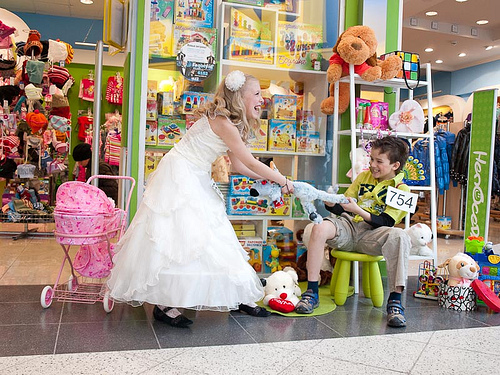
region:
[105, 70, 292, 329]
Blonde girl in a white dress.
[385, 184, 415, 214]
Number 754 on the side of a boy.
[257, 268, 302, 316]
White bear on the floor between two kids.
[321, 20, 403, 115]
Large brown teddy up on a shelf wearing a red shirt.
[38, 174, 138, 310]
Pink stroller with white wheels.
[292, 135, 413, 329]
Brown haired boy sitting on a green stool.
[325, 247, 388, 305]
Light green colored stool that has a boy on it.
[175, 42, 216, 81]
Round circle sign on a glass wall.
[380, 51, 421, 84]
Large rubix cube up on top of a white shelf.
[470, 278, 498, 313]
Red lid lying on the floor.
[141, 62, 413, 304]
two children playing with a toy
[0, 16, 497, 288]
two children in a toy store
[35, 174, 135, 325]
a pink toy stroller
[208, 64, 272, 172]
a little girl smiling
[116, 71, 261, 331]
a girl wearing a frilly white dress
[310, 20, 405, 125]
a stuffed animal on a shelf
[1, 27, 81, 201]
toys hanging on a rack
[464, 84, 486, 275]
a green sign with white letters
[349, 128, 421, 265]
a boy wearing a sign that says 754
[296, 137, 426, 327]
Young boy playing with girl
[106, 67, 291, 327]
Young girl wearing white dress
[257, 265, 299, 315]
White Teddy Bear with a red heart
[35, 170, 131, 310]
Pink Baby Stroller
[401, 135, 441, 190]
Blue Winter Jacket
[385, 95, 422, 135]
White heart box with flower on it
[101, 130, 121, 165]
Girls Stripped Long Sleve Shirt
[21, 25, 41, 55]
Stocking Hat with Tassel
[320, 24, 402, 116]
Stuffed brown dog wearing red shirt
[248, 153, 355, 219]
Blue Stuffed Animal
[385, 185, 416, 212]
identification number pinned to boy's sleeve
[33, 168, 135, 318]
pink doll stroller behind girl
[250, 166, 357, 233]
blue plush dog stretched by children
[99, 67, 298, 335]
girl wearing sheer white gown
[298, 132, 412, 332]
seated boy with one pant leg pushed up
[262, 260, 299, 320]
white bear on ground between children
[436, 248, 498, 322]
tan and white stuffed toy in hat box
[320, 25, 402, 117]
fuzzy brown and caramel dog wearing red shirt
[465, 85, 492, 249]
green company advertising banner behind display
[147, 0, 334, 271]
wall of legos in boxes behind kids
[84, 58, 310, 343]
A young girl in a white dress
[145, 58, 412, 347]
A girl and boy playing tug of war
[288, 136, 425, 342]
A boy dressed in green with the number 754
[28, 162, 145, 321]
A pink play baby carriage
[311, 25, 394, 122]
A stuffed animal dog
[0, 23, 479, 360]
Two kids playing in front of a toy store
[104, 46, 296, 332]
A girl dressed in a wedding dress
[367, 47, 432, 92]
A rubix cube bag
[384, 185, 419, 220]
The number 754 on a card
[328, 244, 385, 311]
A green stool